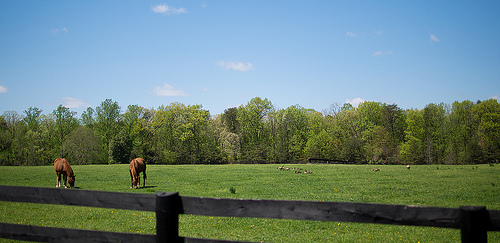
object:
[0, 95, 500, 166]
forest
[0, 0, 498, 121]
blue sky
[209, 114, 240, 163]
trees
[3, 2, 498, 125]
sky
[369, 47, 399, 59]
cloud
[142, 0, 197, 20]
cloud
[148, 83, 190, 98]
cloud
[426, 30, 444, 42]
cloud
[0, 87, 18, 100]
cloud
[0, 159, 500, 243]
field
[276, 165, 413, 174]
several geese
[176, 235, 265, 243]
slat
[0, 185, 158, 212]
slat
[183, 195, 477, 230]
slat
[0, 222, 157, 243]
slat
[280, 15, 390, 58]
three people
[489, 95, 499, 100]
clouds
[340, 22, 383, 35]
clouds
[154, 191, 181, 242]
fence post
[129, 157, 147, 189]
animal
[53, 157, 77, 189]
animal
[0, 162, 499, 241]
pasture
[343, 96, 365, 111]
cloud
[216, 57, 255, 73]
cloud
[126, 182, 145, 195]
grass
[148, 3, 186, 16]
clouds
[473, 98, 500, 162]
trees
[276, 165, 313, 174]
animals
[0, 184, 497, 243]
fence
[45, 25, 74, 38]
cloud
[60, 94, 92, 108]
cloud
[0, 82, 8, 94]
cloud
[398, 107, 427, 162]
trees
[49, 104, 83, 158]
trees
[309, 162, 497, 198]
grass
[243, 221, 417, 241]
grass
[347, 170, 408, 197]
grass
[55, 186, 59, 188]
feet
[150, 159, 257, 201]
grass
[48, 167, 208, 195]
ground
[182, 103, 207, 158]
tree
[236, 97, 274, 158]
tree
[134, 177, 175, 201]
grass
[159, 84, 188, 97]
white cloud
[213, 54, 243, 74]
white cloud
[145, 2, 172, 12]
white cloud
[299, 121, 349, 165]
green tree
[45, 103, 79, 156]
green tree